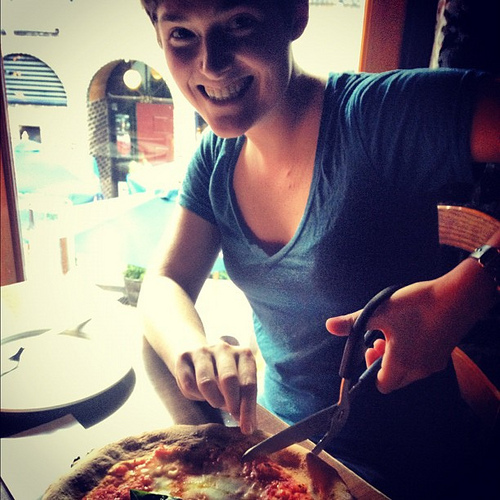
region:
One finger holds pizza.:
[144, 294, 256, 499]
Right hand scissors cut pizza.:
[257, 304, 422, 498]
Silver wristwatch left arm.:
[449, 234, 499, 294]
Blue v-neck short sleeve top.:
[177, 68, 359, 317]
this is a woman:
[51, 0, 491, 499]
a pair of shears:
[217, 270, 446, 478]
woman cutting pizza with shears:
[34, 272, 444, 498]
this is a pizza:
[44, 368, 359, 497]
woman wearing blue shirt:
[176, 34, 491, 439]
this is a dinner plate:
[9, 256, 167, 453]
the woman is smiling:
[140, 6, 353, 141]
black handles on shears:
[331, 259, 418, 415]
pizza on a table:
[12, 248, 396, 498]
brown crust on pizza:
[65, 411, 301, 487]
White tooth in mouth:
[197, 84, 209, 97]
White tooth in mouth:
[204, 84, 220, 97]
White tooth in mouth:
[215, 82, 228, 103]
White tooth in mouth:
[226, 82, 238, 98]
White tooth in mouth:
[235, 80, 244, 89]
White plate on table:
[6, 314, 138, 413]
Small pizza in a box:
[29, 431, 317, 499]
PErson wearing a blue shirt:
[135, 88, 390, 499]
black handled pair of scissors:
[238, 267, 403, 482]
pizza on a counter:
[28, 417, 365, 499]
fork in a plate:
[2, 308, 104, 379]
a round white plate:
[1, 300, 142, 412]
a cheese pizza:
[14, 408, 344, 499]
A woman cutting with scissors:
[158, 282, 439, 482]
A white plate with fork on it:
[8, 294, 125, 450]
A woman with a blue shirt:
[173, 48, 449, 485]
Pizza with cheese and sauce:
[68, 425, 300, 496]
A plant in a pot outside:
[119, 253, 151, 326]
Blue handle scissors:
[283, 286, 398, 471]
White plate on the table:
[34, 342, 126, 409]